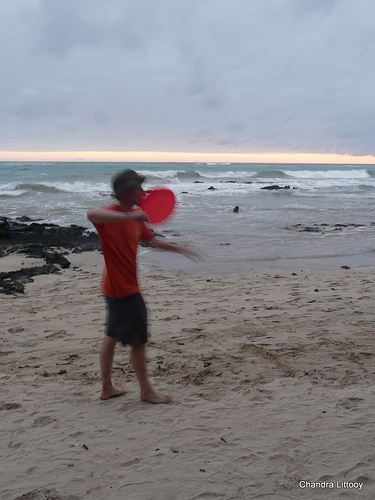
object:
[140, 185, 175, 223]
frisbee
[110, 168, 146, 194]
hat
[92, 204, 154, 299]
shirt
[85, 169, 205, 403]
man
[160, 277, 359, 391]
sand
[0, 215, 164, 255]
rocks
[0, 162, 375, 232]
water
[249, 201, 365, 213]
waves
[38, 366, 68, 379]
footprints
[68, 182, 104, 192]
seafoam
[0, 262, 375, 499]
beach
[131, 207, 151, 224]
hand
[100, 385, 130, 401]
feet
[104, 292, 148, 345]
shorts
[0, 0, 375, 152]
sky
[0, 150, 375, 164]
sunlight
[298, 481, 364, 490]
watermark